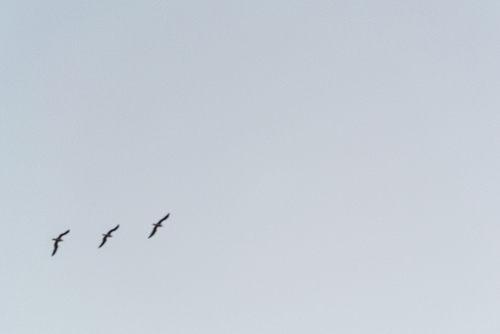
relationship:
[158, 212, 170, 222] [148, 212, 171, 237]
wing of bird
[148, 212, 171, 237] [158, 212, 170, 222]
bird has wing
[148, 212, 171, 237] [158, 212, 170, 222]
bird with wing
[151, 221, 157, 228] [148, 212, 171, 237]
tail of bird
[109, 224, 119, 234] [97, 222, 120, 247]
wing of bird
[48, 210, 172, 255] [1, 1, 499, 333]
birds across sky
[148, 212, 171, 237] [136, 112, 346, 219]
bird flying in sky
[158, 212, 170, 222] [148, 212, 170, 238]
wing of bird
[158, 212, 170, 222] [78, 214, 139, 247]
wing of bird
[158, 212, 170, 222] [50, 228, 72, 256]
wing of birds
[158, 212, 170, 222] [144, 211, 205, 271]
wing of bird